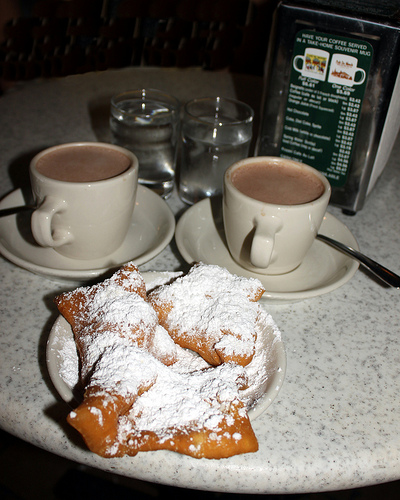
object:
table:
[0, 65, 399, 493]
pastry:
[55, 261, 267, 458]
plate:
[44, 268, 287, 428]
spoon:
[314, 231, 400, 294]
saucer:
[174, 198, 362, 303]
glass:
[172, 94, 253, 207]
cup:
[29, 140, 138, 259]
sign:
[270, 30, 376, 190]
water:
[178, 118, 253, 208]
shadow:
[0, 142, 58, 246]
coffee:
[230, 160, 325, 203]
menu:
[275, 32, 372, 189]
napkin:
[366, 66, 399, 200]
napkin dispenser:
[244, 0, 397, 215]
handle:
[30, 196, 69, 247]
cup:
[222, 155, 330, 275]